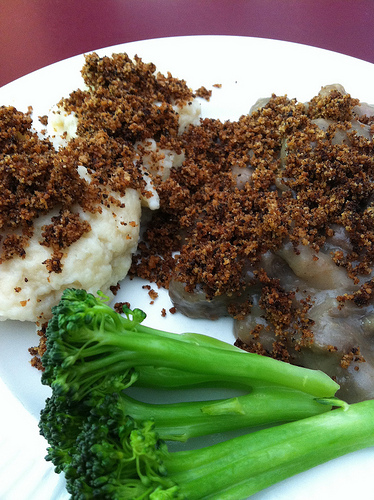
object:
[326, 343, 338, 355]
bits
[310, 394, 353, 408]
spears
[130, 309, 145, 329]
florets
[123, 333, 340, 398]
stalks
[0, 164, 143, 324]
food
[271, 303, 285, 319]
bits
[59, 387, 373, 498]
broccolli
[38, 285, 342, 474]
brocolli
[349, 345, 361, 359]
seasoning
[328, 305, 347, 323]
grave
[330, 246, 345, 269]
seasoning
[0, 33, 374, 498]
plate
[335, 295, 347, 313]
seasoning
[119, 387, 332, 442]
stem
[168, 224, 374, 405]
gravy